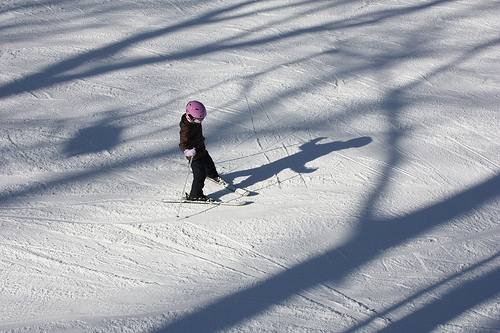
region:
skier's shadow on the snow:
[233, 120, 397, 215]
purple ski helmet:
[185, 86, 213, 123]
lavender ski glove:
[181, 150, 198, 162]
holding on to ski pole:
[173, 148, 207, 226]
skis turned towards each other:
[169, 154, 268, 227]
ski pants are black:
[174, 149, 223, 203]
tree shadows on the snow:
[9, 19, 498, 326]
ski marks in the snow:
[177, 222, 370, 331]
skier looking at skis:
[179, 94, 220, 120]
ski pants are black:
[182, 150, 257, 208]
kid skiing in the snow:
[168, 92, 251, 222]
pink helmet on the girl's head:
[182, 98, 209, 123]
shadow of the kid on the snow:
[267, 120, 384, 195]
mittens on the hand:
[183, 146, 197, 160]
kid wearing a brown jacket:
[173, 94, 240, 206]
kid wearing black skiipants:
[170, 88, 230, 215]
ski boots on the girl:
[184, 189, 214, 203]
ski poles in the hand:
[180, 158, 200, 203]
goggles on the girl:
[194, 119, 201, 124]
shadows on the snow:
[47, 101, 137, 171]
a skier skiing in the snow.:
[179, 100, 236, 211]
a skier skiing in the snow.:
[177, 95, 249, 209]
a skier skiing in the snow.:
[170, 100, 252, 207]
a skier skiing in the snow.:
[173, 100, 248, 206]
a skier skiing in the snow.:
[175, 96, 255, 201]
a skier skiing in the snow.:
[168, 97, 244, 204]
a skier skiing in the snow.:
[160, 99, 248, 206]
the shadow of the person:
[221, 133, 372, 185]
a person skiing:
[145, 103, 268, 206]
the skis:
[171, 180, 261, 203]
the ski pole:
[173, 151, 202, 208]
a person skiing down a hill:
[166, 90, 257, 212]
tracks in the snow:
[85, 215, 387, 330]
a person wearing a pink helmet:
[172, 98, 254, 205]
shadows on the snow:
[41, 9, 472, 94]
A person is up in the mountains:
[11, 37, 482, 309]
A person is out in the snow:
[86, 63, 466, 289]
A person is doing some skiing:
[47, 46, 437, 306]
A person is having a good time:
[21, 41, 462, 331]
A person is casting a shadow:
[65, 36, 441, 311]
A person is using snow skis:
[15, 50, 485, 330]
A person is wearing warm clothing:
[73, 67, 408, 303]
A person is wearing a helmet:
[75, 92, 395, 309]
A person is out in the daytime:
[61, 26, 448, 302]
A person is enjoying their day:
[45, 39, 414, 291]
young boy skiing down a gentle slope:
[156, 83, 275, 242]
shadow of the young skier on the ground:
[219, 113, 373, 212]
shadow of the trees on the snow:
[214, 87, 490, 332]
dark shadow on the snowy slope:
[61, 111, 127, 160]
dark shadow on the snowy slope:
[206, 128, 378, 204]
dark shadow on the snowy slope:
[0, 145, 180, 208]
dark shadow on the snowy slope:
[380, 263, 495, 331]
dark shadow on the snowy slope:
[463, 313, 498, 332]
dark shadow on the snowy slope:
[342, 254, 497, 331]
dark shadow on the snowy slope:
[55, 33, 345, 159]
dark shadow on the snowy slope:
[1, 0, 461, 95]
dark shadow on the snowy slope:
[0, 0, 130, 37]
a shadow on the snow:
[252, 111, 374, 196]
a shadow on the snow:
[372, 274, 487, 331]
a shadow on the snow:
[154, 237, 324, 328]